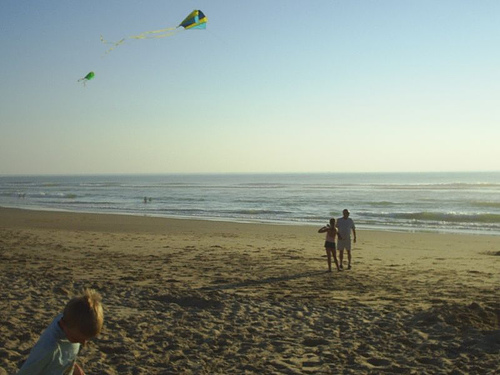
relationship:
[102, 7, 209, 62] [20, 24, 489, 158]
kite in sky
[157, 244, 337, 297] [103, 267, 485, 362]
shadow on ground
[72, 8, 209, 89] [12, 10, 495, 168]
kites in sky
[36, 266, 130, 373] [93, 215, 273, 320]
boy playing on beach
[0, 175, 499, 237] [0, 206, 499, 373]
waves crashing against shore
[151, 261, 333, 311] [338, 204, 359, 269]
shadow of standing people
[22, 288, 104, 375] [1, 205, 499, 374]
boy looking at ground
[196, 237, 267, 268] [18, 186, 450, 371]
sand on beach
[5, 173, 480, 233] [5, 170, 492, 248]
water on ocean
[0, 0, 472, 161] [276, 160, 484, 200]
sky above water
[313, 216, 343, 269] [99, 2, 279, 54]
person flying kite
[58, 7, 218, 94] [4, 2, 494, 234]
kite flying in sky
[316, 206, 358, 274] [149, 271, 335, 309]
people have shadow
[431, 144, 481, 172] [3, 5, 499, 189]
lightest part of sky